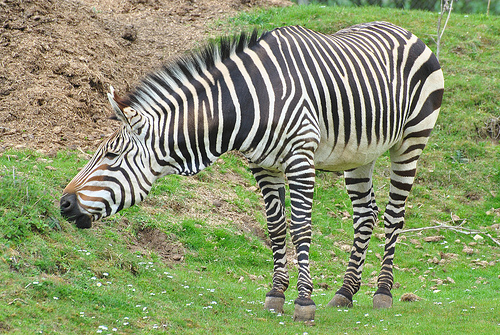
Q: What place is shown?
A: It is a field.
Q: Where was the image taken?
A: It was taken at the field.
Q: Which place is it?
A: It is a field.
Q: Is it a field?
A: Yes, it is a field.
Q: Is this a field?
A: Yes, it is a field.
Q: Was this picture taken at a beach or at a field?
A: It was taken at a field.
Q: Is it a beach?
A: No, it is a field.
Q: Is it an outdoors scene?
A: Yes, it is outdoors.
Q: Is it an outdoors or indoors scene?
A: It is outdoors.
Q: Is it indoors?
A: No, it is outdoors.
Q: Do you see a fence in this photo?
A: No, there are no fences.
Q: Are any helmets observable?
A: No, there are no helmets.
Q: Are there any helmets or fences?
A: No, there are no helmets or fences.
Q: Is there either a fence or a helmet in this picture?
A: No, there are no helmets or fences.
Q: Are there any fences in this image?
A: No, there are no fences.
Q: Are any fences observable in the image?
A: No, there are no fences.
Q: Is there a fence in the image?
A: No, there are no fences.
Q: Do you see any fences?
A: No, there are no fences.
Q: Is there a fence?
A: No, there are no fences.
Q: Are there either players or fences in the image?
A: No, there are no fences or players.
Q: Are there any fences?
A: No, there are no fences.